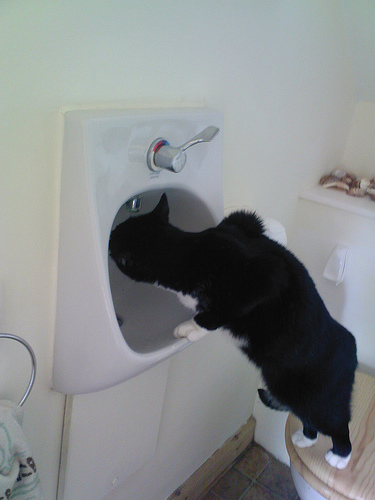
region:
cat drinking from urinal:
[50, 105, 226, 394]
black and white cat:
[108, 192, 356, 470]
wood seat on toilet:
[285, 371, 372, 499]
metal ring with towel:
[1, 332, 36, 498]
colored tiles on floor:
[208, 442, 293, 498]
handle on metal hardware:
[146, 125, 219, 174]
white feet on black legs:
[291, 429, 354, 469]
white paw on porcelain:
[168, 320, 202, 347]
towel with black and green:
[1, 400, 37, 497]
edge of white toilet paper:
[262, 218, 287, 243]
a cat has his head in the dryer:
[83, 174, 314, 371]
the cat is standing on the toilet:
[151, 283, 370, 443]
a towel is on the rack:
[1, 384, 20, 494]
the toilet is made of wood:
[252, 401, 349, 490]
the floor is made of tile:
[223, 463, 297, 498]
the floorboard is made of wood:
[100, 406, 288, 466]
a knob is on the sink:
[135, 123, 255, 186]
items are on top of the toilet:
[312, 163, 360, 217]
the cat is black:
[98, 201, 344, 338]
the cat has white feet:
[288, 414, 349, 487]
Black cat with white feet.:
[95, 171, 373, 452]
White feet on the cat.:
[285, 422, 373, 483]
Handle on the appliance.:
[135, 96, 258, 188]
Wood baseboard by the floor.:
[200, 425, 254, 477]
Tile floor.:
[235, 432, 281, 498]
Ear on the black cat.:
[142, 189, 176, 224]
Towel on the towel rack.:
[1, 320, 64, 498]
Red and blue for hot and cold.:
[148, 129, 182, 170]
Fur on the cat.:
[191, 195, 299, 350]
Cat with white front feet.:
[109, 176, 281, 372]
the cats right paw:
[290, 428, 320, 446]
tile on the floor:
[234, 465, 276, 493]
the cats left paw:
[322, 446, 350, 469]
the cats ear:
[116, 242, 140, 267]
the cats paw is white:
[174, 320, 206, 339]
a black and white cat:
[115, 212, 349, 389]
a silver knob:
[158, 149, 187, 173]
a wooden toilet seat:
[353, 406, 373, 444]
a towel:
[0, 434, 40, 496]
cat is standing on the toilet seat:
[145, 234, 358, 456]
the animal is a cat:
[110, 193, 359, 469]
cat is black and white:
[108, 192, 357, 466]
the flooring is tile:
[193, 442, 301, 497]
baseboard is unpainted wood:
[163, 414, 255, 498]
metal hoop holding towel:
[0, 333, 40, 498]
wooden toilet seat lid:
[285, 366, 373, 498]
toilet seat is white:
[288, 461, 329, 497]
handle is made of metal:
[150, 123, 219, 174]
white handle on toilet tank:
[318, 247, 351, 286]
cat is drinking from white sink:
[47, 103, 228, 396]